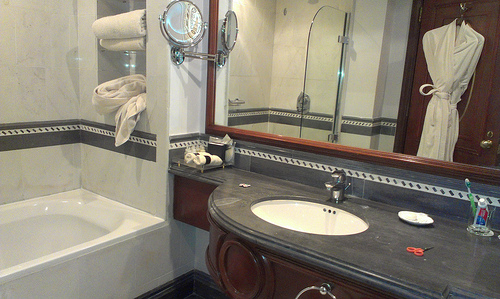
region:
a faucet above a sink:
[319, 161, 351, 206]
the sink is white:
[248, 163, 373, 241]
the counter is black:
[186, 150, 496, 297]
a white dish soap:
[395, 202, 435, 227]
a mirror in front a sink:
[202, 3, 499, 232]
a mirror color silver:
[156, 5, 239, 80]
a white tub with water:
[0, 183, 175, 298]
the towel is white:
[89, 7, 152, 64]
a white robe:
[403, 0, 488, 164]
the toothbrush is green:
[458, 173, 477, 220]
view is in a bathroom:
[153, 15, 482, 274]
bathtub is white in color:
[13, 194, 153, 291]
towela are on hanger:
[90, 17, 157, 127]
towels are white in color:
[88, 15, 171, 118]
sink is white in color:
[271, 177, 349, 241]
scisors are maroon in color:
[386, 229, 431, 268]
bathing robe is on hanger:
[404, 14, 499, 167]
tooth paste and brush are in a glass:
[456, 179, 499, 234]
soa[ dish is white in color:
[402, 199, 442, 236]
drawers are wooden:
[212, 239, 303, 295]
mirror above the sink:
[205, 3, 490, 172]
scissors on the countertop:
[399, 238, 433, 256]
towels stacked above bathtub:
[95, 10, 152, 146]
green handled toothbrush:
[460, 176, 482, 223]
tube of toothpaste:
[473, 195, 489, 230]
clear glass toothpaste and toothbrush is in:
[469, 196, 493, 241]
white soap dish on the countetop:
[398, 206, 438, 228]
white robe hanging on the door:
[396, 11, 487, 160]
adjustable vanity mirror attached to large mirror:
[163, 7, 220, 66]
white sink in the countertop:
[250, 195, 374, 249]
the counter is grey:
[371, 233, 390, 260]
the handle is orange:
[405, 245, 424, 258]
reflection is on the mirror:
[220, 7, 490, 176]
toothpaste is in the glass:
[466, 192, 488, 233]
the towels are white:
[87, 69, 149, 131]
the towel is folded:
[86, 10, 157, 45]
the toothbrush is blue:
[461, 182, 477, 206]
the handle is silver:
[280, 277, 340, 296]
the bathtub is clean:
[12, 206, 150, 258]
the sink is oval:
[255, 182, 378, 241]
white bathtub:
[1, 183, 166, 291]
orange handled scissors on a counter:
[406, 243, 436, 255]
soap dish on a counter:
[398, 208, 435, 230]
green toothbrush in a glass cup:
[463, 175, 478, 218]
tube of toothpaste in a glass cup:
[473, 196, 488, 233]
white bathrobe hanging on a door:
[414, 17, 486, 158]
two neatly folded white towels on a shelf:
[86, 6, 148, 52]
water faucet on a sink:
[323, 165, 350, 206]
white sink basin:
[248, 192, 370, 240]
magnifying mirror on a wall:
[158, 0, 222, 72]